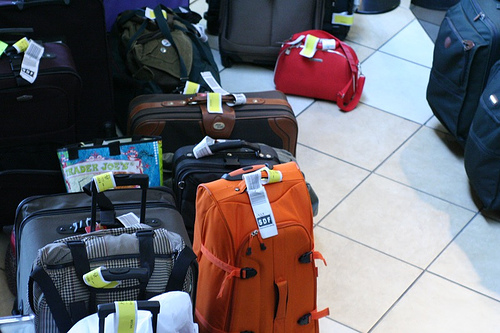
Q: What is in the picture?
A: Luggage.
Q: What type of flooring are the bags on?
A: Tile.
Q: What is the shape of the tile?
A: Square.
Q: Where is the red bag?
A: Middle top.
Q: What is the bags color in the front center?
A: Orange.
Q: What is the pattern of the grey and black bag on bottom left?
A: Checkered.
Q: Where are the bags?
A: On the floor.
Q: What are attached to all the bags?
A: Tags.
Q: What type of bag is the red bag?
A: Over the shoulder bag.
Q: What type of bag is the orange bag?
A: Suitcase.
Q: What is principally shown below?
A: Luggage.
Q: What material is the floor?
A: Tiles.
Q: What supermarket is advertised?
A: Trader Joe's.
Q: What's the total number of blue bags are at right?
A: 2.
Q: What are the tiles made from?
A: Ceramic.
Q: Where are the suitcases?
A: Inside a terminal.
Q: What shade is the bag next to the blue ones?
A: Red.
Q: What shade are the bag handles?
A: Black.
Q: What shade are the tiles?
A: Tan.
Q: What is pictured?
A: Luggage.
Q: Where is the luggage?
A: On the floor.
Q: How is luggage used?
A: To transport goods.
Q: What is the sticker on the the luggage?
A: The destination of the bag.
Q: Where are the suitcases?
A: Sitting on the floor.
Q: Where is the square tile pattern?
A: On the floor.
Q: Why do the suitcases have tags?
A: For identification.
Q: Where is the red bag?
A: In the background, on the floor.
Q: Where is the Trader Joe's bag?
A: Near the black suitcase.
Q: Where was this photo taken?
A: At an airport.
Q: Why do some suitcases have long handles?
A: To be pulled on wheels.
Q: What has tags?
A: Luggage.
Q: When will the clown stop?
A: No clown.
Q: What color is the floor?
A: White.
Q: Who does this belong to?
A: Passengers.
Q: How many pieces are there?
A: Fourteen.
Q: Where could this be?
A: Airport.